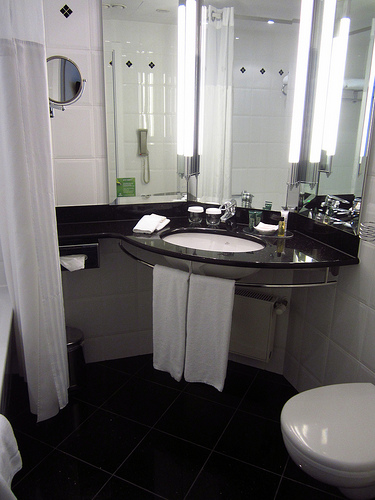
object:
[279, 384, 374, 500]
toilet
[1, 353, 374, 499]
floor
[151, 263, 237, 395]
towels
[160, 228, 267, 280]
sink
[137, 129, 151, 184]
phone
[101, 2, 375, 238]
mirror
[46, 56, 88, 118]
mirror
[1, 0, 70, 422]
curtain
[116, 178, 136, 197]
sticker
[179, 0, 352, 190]
lights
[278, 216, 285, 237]
bottle oil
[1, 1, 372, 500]
bathroom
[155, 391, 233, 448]
tile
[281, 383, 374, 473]
toilet seat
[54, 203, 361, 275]
counter-top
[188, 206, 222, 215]
covers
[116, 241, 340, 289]
bar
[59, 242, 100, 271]
dispenser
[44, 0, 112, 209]
wall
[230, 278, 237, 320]
edge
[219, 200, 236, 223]
faucet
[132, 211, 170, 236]
wash cloth